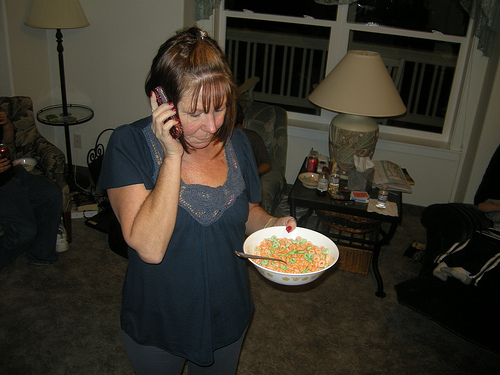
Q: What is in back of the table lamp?
A: The window.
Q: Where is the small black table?
A: Next to the black arm chair.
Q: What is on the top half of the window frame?
A: 2 locks.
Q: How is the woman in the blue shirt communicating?
A: The woman is using a cellphone.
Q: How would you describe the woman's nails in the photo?
A: They are painted red.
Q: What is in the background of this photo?
A: A small black table.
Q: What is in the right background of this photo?
A: A black floor lamp.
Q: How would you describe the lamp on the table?
A: A green table lamp.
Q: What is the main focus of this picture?
A: A woman on her phone.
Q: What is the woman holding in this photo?
A: A bowl of cereal.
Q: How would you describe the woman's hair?
A: Brown.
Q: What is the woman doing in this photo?
A: She is looking down.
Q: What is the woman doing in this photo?
A: On her cell phone.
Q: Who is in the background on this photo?
A: A person.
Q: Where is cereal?
A: In a bowl.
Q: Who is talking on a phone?
A: A woman.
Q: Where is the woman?
A: In a living room.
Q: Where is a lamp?
A: On small table.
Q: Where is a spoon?
A: In the bowl.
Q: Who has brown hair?
A: The woman.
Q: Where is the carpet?
A: On the floor.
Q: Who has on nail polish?
A: Woman on phone.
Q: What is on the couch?
A: A person.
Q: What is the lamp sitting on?
A: A side table.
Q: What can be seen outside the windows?
A: A porch rail.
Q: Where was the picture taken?
A: In a room.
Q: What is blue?
A: Woman's shirt.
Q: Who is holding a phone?
A: A woman.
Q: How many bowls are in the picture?
A: One.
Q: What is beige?
A: Lamp shades.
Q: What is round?
A: A bowl.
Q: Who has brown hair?
A: The woman.